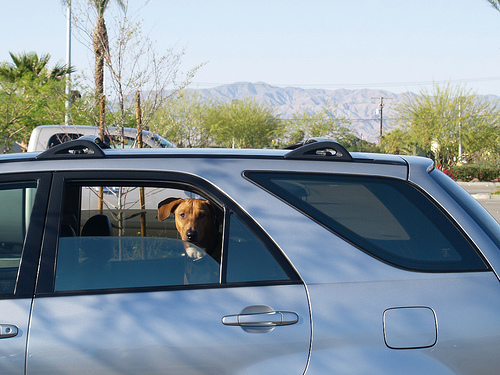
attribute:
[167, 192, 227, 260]
dog — brown, looking, window, car, black, flop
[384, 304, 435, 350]
tank — gas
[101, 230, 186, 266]
window — glass, down, dog, rolled, cracked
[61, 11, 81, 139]
pole — gray, telephoe, flag, tele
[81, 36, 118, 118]
tree — palm, back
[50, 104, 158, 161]
truck — grey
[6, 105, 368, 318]
car — silver, black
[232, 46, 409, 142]
mountain — piece, back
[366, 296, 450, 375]
gas — ope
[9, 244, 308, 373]
door — silver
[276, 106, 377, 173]
rack — luggage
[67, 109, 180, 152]
suv — silver